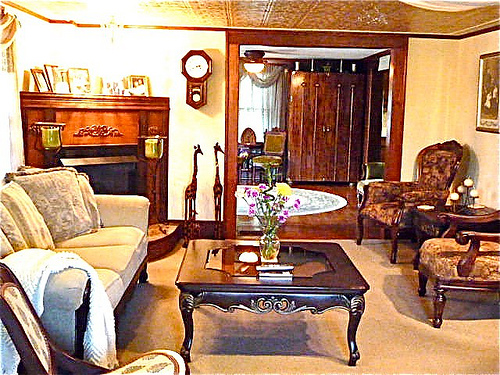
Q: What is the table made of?
A: Wood.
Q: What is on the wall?
A: Clock.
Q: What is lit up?
A: The room.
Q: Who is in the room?
A: No people.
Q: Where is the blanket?
A: On couch.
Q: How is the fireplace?
A: Decorative.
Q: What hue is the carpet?
A: Beige.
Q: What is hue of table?
A: Dark cherry.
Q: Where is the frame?
A: On chair.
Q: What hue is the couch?
A: Tan.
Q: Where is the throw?
A: On couch.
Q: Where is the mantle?
A: Over fireplace.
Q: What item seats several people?
A: A couch.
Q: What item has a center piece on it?
A: A coffee table.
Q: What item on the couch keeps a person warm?
A: A blanket.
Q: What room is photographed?
A: Living room.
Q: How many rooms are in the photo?
A: Two.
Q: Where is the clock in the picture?
A: The wall.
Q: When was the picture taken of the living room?
A: Daytime.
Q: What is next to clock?
A: A fireplace.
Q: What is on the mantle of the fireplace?
A: Framed pictures.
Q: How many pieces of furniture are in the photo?
A: Five.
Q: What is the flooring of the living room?
A: Carpet.